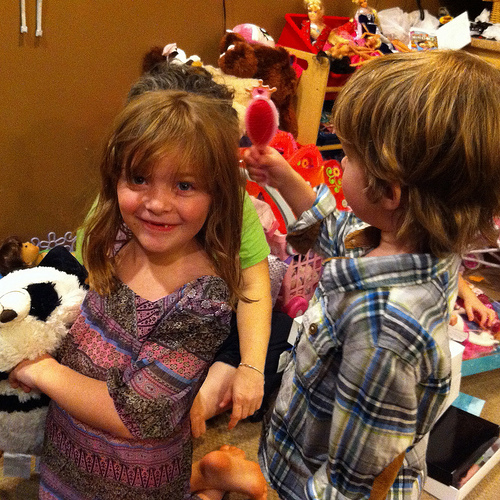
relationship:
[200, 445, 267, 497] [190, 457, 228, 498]
feet with ankles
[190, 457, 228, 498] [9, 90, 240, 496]
ankles of girl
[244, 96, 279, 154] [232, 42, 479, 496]
brush held by boy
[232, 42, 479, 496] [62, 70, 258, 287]
boy attempting to brush hair